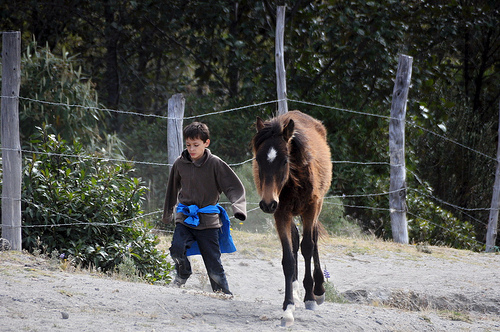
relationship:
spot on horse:
[266, 143, 278, 162] [234, 110, 336, 323]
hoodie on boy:
[163, 149, 248, 228] [158, 118, 244, 300]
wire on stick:
[5, 94, 187, 123] [1, 29, 23, 250]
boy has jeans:
[158, 118, 244, 300] [168, 222, 232, 294]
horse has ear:
[234, 110, 336, 323] [279, 120, 297, 139]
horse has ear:
[234, 110, 336, 323] [253, 112, 267, 131]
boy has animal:
[158, 118, 244, 300] [234, 110, 336, 323]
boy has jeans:
[158, 118, 244, 300] [171, 222, 225, 290]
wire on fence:
[5, 94, 187, 123] [190, 95, 280, 115]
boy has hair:
[158, 118, 244, 300] [186, 124, 211, 140]